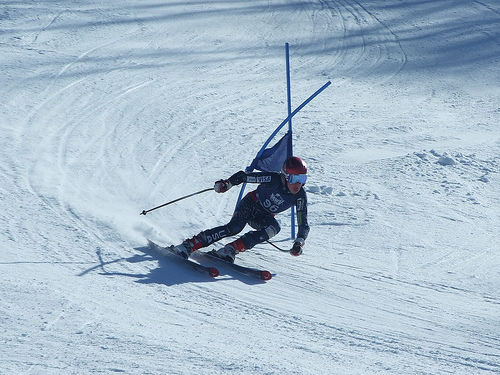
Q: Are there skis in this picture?
A: Yes, there are skis.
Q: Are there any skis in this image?
A: Yes, there are skis.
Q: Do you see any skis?
A: Yes, there are skis.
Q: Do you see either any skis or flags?
A: Yes, there are skis.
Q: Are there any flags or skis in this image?
A: Yes, there are skis.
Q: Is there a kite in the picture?
A: No, there are no kites.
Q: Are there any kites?
A: No, there are no kites.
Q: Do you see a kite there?
A: No, there are no kites.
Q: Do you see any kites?
A: No, there are no kites.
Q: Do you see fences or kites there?
A: No, there are no kites or fences.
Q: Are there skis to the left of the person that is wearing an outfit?
A: Yes, there are skis to the left of the person.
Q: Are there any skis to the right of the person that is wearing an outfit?
A: No, the skis are to the left of the person.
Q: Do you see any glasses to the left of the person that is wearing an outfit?
A: No, there are skis to the left of the person.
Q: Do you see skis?
A: Yes, there are skis.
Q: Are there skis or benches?
A: Yes, there are skis.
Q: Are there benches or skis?
A: Yes, there are skis.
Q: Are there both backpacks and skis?
A: No, there are skis but no backpacks.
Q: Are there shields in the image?
A: No, there are no shields.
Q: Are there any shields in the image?
A: No, there are no shields.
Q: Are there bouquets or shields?
A: No, there are no shields or bouquets.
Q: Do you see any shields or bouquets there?
A: No, there are no shields or bouquets.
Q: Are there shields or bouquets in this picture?
A: No, there are no shields or bouquets.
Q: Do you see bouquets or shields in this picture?
A: No, there are no shields or bouquets.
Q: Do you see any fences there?
A: No, there are no fences.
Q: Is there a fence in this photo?
A: No, there are no fences.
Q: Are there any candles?
A: No, there are no candles.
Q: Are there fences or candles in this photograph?
A: No, there are no candles or fences.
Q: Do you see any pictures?
A: No, there are no pictures.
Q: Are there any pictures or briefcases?
A: No, there are no pictures or briefcases.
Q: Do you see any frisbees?
A: No, there are no frisbees.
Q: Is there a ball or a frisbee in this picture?
A: No, there are no frisbees or balls.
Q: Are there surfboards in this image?
A: No, there are no surfboards.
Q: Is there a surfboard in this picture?
A: No, there are no surfboards.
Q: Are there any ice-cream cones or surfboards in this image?
A: No, there are no surfboards or ice-cream cones.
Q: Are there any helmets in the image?
A: Yes, there is a helmet.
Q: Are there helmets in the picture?
A: Yes, there is a helmet.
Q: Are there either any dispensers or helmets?
A: Yes, there is a helmet.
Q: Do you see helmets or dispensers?
A: Yes, there is a helmet.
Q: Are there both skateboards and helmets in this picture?
A: No, there is a helmet but no skateboards.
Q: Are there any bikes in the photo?
A: No, there are no bikes.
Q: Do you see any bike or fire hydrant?
A: No, there are no bikes or fire hydrants.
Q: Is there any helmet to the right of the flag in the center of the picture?
A: Yes, there is a helmet to the right of the flag.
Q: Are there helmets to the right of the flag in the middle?
A: Yes, there is a helmet to the right of the flag.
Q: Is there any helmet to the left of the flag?
A: No, the helmet is to the right of the flag.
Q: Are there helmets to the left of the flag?
A: No, the helmet is to the right of the flag.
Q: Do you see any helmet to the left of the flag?
A: No, the helmet is to the right of the flag.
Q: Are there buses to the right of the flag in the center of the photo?
A: No, there is a helmet to the right of the flag.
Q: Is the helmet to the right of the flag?
A: Yes, the helmet is to the right of the flag.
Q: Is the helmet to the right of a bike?
A: No, the helmet is to the right of the flag.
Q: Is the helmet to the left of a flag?
A: No, the helmet is to the right of a flag.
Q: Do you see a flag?
A: Yes, there is a flag.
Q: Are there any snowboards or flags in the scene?
A: Yes, there is a flag.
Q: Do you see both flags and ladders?
A: No, there is a flag but no ladders.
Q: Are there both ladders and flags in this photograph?
A: No, there is a flag but no ladders.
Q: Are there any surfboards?
A: No, there are no surfboards.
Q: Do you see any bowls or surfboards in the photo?
A: No, there are no surfboards or bowls.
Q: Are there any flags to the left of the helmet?
A: Yes, there is a flag to the left of the helmet.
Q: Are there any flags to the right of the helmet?
A: No, the flag is to the left of the helmet.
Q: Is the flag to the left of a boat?
A: No, the flag is to the left of the helmet.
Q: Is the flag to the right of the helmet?
A: No, the flag is to the left of the helmet.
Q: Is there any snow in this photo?
A: Yes, there is snow.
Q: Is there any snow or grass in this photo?
A: Yes, there is snow.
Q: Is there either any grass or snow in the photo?
A: Yes, there is snow.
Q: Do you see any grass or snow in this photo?
A: Yes, there is snow.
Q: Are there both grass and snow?
A: No, there is snow but no grass.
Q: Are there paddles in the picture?
A: No, there are no paddles.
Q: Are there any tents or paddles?
A: No, there are no paddles or tents.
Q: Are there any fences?
A: No, there are no fences.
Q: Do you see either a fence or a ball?
A: No, there are no fences or balls.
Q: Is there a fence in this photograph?
A: No, there are no fences.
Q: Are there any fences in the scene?
A: No, there are no fences.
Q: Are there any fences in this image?
A: No, there are no fences.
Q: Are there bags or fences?
A: No, there are no fences or bags.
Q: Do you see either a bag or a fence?
A: No, there are no fences or bags.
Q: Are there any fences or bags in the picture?
A: No, there are no fences or bags.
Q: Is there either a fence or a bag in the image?
A: No, there are no fences or bags.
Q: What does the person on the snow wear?
A: The person wears an outfit.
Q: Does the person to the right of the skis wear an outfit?
A: Yes, the person wears an outfit.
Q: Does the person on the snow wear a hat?
A: No, the person wears an outfit.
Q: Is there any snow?
A: Yes, there is snow.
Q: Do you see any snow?
A: Yes, there is snow.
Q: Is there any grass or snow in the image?
A: Yes, there is snow.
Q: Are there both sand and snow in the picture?
A: No, there is snow but no sand.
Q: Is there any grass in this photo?
A: No, there is no grass.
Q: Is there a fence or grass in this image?
A: No, there are no grass or fences.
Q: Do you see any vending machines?
A: No, there are no vending machines.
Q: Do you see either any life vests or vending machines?
A: No, there are no vending machines or life vests.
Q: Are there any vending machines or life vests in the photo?
A: No, there are no vending machines or life vests.